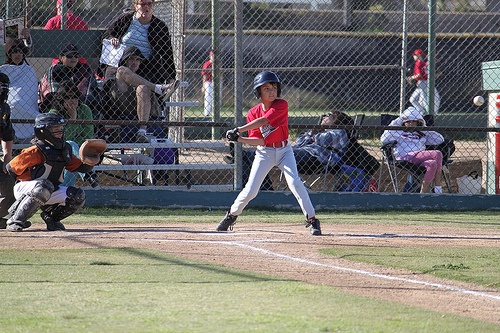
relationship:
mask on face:
[50, 115, 76, 145] [44, 117, 67, 127]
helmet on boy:
[237, 56, 291, 104] [209, 70, 296, 199]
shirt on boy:
[251, 99, 305, 148] [209, 70, 296, 199]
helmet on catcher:
[237, 56, 291, 104] [19, 107, 123, 206]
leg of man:
[110, 59, 158, 94] [108, 20, 180, 145]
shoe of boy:
[217, 206, 249, 237] [209, 70, 296, 199]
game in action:
[36, 5, 464, 330] [86, 65, 470, 326]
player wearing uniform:
[404, 49, 444, 121] [401, 60, 431, 112]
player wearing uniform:
[195, 53, 231, 114] [197, 64, 227, 116]